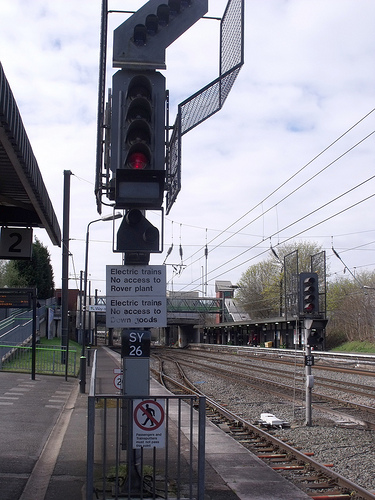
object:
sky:
[0, 0, 374, 302]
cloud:
[29, 80, 89, 115]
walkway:
[68, 328, 240, 495]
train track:
[153, 338, 374, 499]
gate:
[89, 394, 206, 499]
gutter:
[44, 375, 76, 410]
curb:
[210, 348, 299, 412]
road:
[0, 294, 45, 363]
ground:
[6, 376, 87, 500]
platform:
[188, 314, 326, 353]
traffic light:
[97, 0, 210, 213]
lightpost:
[122, 209, 145, 477]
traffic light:
[298, 270, 320, 322]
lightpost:
[305, 346, 313, 429]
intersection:
[154, 347, 186, 371]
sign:
[105, 265, 166, 328]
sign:
[0, 231, 34, 259]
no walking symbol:
[135, 401, 164, 431]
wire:
[165, 101, 374, 276]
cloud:
[239, 83, 317, 126]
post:
[78, 354, 86, 393]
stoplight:
[128, 149, 149, 170]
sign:
[133, 400, 167, 449]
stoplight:
[306, 302, 316, 313]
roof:
[0, 60, 61, 250]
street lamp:
[81, 211, 122, 376]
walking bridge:
[92, 294, 231, 327]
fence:
[0, 342, 80, 375]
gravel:
[349, 460, 371, 479]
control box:
[261, 413, 293, 430]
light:
[308, 278, 316, 286]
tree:
[323, 276, 355, 312]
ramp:
[224, 294, 257, 319]